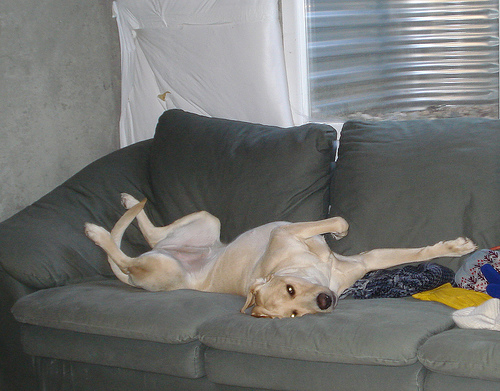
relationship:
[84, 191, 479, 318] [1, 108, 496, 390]
dog on couch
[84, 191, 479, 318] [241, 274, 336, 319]
dog has head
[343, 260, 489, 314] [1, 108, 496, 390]
objects on couch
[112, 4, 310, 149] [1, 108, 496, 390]
sheet behind couch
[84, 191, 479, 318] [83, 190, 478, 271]
dog has legs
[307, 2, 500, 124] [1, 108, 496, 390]
blinds behind couch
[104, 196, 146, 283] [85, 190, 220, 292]
tail between legs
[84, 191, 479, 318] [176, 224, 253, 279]
dog has belly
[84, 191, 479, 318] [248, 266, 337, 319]
dog has face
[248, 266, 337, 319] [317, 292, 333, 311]
face has nose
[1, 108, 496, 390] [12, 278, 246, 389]
couch has cushion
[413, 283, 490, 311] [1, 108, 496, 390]
glove on couch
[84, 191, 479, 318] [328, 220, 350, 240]
dog has paw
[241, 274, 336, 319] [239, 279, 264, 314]
head has ear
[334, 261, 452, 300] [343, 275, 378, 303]
blanket has fringe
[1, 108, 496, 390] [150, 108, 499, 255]
couch has pillows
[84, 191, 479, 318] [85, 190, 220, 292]
dog has back legs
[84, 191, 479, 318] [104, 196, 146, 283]
dog has tail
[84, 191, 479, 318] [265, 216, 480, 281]
dog has front legs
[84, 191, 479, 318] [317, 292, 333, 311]
dog has nose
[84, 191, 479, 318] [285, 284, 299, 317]
dog has eyes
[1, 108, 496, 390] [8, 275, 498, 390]
couch has cushions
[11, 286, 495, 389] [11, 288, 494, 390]
cushions has edge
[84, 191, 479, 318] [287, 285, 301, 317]
dog has eyeballs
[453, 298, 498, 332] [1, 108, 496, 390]
object on couch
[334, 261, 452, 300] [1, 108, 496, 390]
blanket on couch